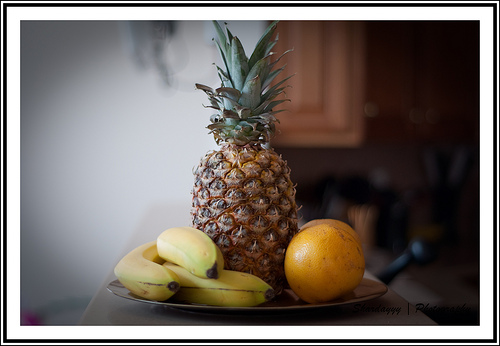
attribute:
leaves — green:
[210, 20, 287, 149]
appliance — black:
[375, 231, 435, 287]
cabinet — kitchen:
[265, 27, 364, 154]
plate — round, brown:
[102, 267, 389, 318]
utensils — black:
[423, 138, 495, 253]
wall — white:
[18, 22, 270, 327]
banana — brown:
[108, 208, 282, 310]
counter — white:
[87, 200, 439, 330]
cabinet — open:
[253, 17, 371, 152]